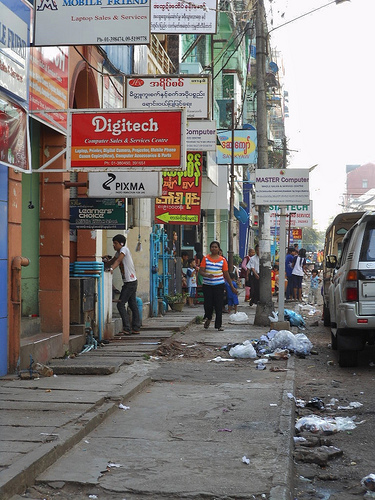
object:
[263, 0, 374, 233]
sky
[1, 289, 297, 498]
sidewalk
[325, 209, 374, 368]
car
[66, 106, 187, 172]
board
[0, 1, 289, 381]
building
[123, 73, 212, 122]
board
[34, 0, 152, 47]
board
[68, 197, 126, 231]
board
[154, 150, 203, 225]
board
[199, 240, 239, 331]
person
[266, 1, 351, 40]
light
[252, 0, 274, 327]
pole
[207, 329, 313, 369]
garbage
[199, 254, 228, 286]
shirt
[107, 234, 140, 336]
man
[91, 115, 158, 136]
digitech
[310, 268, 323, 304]
child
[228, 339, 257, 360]
bag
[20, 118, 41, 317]
door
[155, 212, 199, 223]
arrow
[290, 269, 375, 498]
road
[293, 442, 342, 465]
rock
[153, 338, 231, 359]
dip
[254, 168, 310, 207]
sign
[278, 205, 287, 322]
pole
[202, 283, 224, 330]
pants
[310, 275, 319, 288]
shirt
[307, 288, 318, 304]
pants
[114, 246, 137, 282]
shirt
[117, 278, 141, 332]
pants